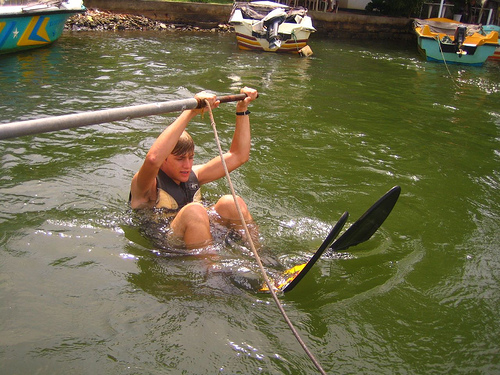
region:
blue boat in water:
[418, 14, 498, 72]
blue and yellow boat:
[1, 2, 79, 52]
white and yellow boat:
[230, 6, 312, 58]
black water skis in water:
[271, 188, 401, 311]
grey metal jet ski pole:
[3, 88, 250, 137]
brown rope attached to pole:
[204, 109, 338, 373]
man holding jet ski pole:
[136, 89, 403, 309]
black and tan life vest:
[137, 170, 207, 234]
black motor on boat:
[455, 25, 465, 55]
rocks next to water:
[77, 15, 229, 38]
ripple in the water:
[338, 114, 393, 158]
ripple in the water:
[219, 341, 279, 363]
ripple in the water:
[376, 338, 416, 365]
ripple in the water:
[39, 334, 125, 359]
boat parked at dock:
[211, 2, 325, 57]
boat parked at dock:
[403, 9, 490, 70]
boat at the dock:
[0, 9, 87, 47]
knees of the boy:
[169, 200, 254, 235]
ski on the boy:
[309, 214, 341, 280]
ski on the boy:
[365, 169, 421, 237]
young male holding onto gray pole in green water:
[121, 129, 245, 229]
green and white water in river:
[11, 293, 92, 340]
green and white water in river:
[99, 329, 189, 347]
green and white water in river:
[214, 323, 286, 369]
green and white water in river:
[16, 212, 83, 241]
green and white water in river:
[92, 204, 114, 240]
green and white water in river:
[272, 212, 312, 239]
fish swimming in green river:
[339, 134, 406, 168]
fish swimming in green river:
[36, 220, 101, 250]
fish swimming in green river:
[219, 334, 269, 366]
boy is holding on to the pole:
[140, 89, 263, 152]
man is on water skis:
[171, 187, 398, 312]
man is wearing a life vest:
[153, 144, 230, 240]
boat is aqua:
[427, 27, 494, 70]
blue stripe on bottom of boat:
[429, 52, 487, 72]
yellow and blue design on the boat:
[23, 15, 65, 47]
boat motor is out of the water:
[247, 4, 297, 58]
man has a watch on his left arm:
[227, 102, 256, 126]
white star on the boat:
[12, 28, 22, 40]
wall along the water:
[315, 9, 415, 52]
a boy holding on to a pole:
[106, 82, 430, 340]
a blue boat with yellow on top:
[412, 19, 494, 94]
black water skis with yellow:
[274, 182, 419, 333]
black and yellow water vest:
[153, 169, 229, 265]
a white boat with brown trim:
[216, 6, 331, 78]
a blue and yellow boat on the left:
[3, 3, 103, 65]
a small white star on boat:
[6, 26, 26, 45]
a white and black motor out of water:
[251, 5, 302, 57]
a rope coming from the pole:
[198, 93, 362, 372]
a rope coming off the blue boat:
[436, 28, 471, 100]